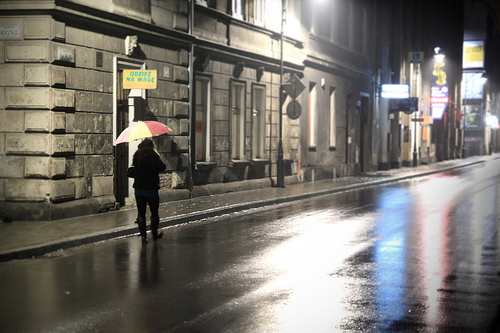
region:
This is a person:
[61, 88, 206, 247]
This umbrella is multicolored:
[107, 118, 168, 138]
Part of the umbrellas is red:
[142, 117, 170, 145]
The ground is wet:
[193, 179, 387, 331]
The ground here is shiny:
[221, 203, 439, 323]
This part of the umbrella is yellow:
[124, 120, 149, 142]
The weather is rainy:
[41, 63, 497, 283]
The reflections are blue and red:
[367, 170, 470, 311]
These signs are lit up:
[406, 51, 498, 129]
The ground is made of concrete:
[31, 255, 196, 321]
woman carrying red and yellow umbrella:
[112, 118, 173, 243]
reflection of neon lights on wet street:
[367, 168, 469, 320]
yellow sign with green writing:
[120, 65, 159, 88]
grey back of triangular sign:
[282, 73, 306, 100]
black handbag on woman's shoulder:
[123, 157, 138, 179]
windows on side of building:
[187, 74, 268, 173]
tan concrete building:
[11, 6, 386, 226]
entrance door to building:
[355, 88, 376, 174]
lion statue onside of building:
[125, 33, 140, 57]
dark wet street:
[222, 210, 417, 328]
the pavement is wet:
[211, 223, 270, 295]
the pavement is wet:
[248, 214, 323, 293]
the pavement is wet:
[386, 164, 453, 253]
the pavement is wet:
[280, 260, 366, 330]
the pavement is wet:
[343, 232, 451, 324]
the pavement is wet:
[317, 194, 420, 265]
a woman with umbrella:
[118, 104, 180, 228]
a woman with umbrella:
[87, 112, 198, 281]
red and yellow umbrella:
[104, 112, 173, 147]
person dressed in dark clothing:
[131, 139, 168, 248]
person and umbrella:
[105, 109, 178, 234]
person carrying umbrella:
[127, 138, 168, 233]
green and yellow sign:
[117, 61, 159, 95]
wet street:
[0, 156, 498, 331]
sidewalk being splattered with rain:
[3, 139, 498, 259]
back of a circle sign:
[284, 98, 302, 123]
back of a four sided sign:
[273, 68, 309, 98]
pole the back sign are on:
[276, 4, 287, 175]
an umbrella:
[122, 116, 166, 144]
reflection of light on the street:
[254, 215, 366, 332]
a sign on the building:
[125, 70, 161, 87]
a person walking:
[129, 155, 166, 232]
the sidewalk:
[225, 190, 269, 210]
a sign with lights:
[380, 80, 412, 100]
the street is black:
[367, 185, 484, 310]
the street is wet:
[305, 196, 452, 316]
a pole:
[273, 33, 289, 82]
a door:
[228, 80, 254, 162]